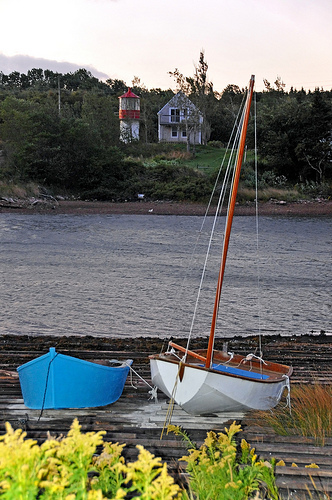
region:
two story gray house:
[154, 85, 210, 149]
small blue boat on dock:
[12, 342, 136, 427]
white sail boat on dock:
[148, 345, 296, 437]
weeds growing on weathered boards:
[294, 378, 330, 466]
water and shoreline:
[71, 199, 145, 227]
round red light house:
[114, 79, 144, 151]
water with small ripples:
[20, 285, 121, 328]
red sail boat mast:
[200, 63, 266, 292]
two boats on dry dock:
[11, 288, 303, 429]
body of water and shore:
[263, 206, 327, 306]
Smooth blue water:
[3, 213, 182, 333]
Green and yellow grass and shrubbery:
[4, 418, 243, 498]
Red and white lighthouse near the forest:
[113, 73, 149, 144]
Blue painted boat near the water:
[10, 320, 138, 409]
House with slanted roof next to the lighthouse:
[111, 74, 207, 148]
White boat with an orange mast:
[155, 62, 285, 431]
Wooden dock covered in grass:
[168, 405, 297, 439]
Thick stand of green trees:
[8, 83, 112, 181]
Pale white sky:
[60, 11, 324, 59]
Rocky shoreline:
[92, 201, 197, 223]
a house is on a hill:
[156, 91, 212, 150]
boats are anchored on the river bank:
[8, 336, 330, 473]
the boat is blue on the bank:
[14, 343, 131, 413]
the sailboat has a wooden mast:
[151, 74, 294, 421]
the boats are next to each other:
[14, 74, 294, 421]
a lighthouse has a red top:
[113, 85, 144, 146]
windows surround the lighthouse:
[115, 87, 145, 122]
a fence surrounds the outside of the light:
[112, 104, 141, 117]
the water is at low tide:
[6, 188, 328, 376]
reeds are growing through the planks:
[240, 379, 330, 459]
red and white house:
[115, 86, 143, 153]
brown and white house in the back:
[156, 85, 224, 144]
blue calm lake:
[0, 212, 323, 342]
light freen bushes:
[5, 418, 261, 494]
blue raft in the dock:
[15, 347, 128, 412]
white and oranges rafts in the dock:
[152, 343, 294, 412]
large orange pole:
[206, 65, 264, 369]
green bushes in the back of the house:
[1, 58, 321, 210]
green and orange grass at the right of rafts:
[263, 384, 331, 439]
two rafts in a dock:
[4, 344, 297, 426]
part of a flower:
[218, 469, 226, 475]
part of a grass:
[302, 399, 315, 422]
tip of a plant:
[63, 424, 82, 441]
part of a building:
[163, 129, 169, 133]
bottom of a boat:
[78, 395, 83, 420]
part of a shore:
[275, 198, 283, 202]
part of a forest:
[94, 127, 105, 144]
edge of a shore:
[70, 160, 89, 168]